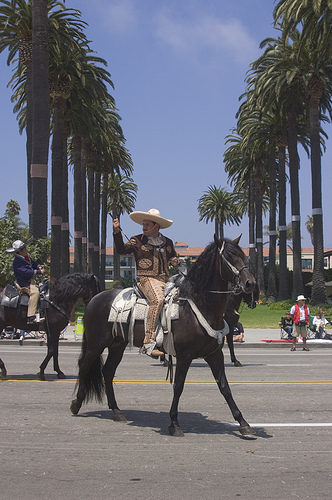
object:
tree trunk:
[100, 169, 108, 291]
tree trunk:
[93, 167, 101, 277]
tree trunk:
[72, 151, 87, 271]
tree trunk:
[60, 117, 69, 276]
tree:
[46, 0, 71, 297]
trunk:
[309, 67, 326, 293]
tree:
[276, 0, 330, 304]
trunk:
[291, 141, 302, 303]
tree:
[259, 32, 294, 298]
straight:
[278, 138, 289, 298]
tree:
[242, 66, 265, 300]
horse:
[71, 232, 260, 441]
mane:
[185, 233, 227, 289]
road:
[1, 337, 332, 496]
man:
[5, 237, 49, 325]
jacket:
[11, 253, 38, 288]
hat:
[6, 235, 35, 254]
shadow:
[69, 409, 272, 440]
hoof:
[242, 425, 258, 441]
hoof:
[169, 421, 185, 437]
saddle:
[108, 283, 180, 323]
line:
[231, 419, 329, 427]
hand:
[112, 217, 119, 229]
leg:
[139, 278, 164, 340]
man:
[112, 207, 179, 360]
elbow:
[116, 244, 126, 255]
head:
[213, 233, 257, 295]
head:
[129, 207, 174, 237]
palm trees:
[0, 0, 78, 235]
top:
[113, 230, 180, 277]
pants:
[137, 267, 184, 348]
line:
[0, 380, 330, 387]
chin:
[143, 231, 149, 237]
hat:
[128, 208, 172, 229]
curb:
[1, 333, 321, 349]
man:
[290, 293, 311, 351]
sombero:
[128, 208, 172, 230]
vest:
[292, 303, 309, 325]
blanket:
[110, 272, 184, 322]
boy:
[277, 311, 293, 340]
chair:
[280, 326, 293, 341]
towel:
[262, 338, 297, 342]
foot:
[145, 344, 165, 356]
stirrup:
[142, 341, 161, 356]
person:
[225, 313, 242, 344]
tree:
[252, 36, 279, 300]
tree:
[222, 128, 260, 270]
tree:
[91, 109, 133, 277]